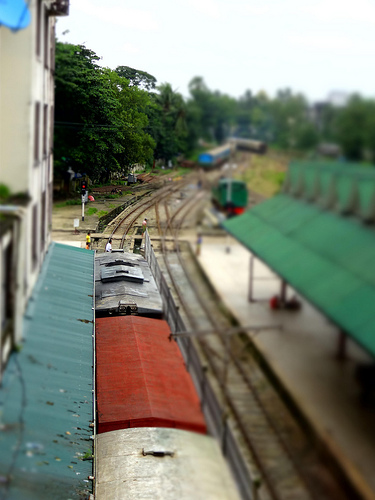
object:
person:
[86, 242, 90, 250]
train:
[92, 248, 245, 499]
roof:
[94, 251, 165, 316]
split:
[90, 232, 189, 242]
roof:
[0, 240, 95, 500]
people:
[75, 186, 94, 223]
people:
[86, 232, 91, 247]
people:
[106, 240, 112, 253]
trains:
[199, 141, 236, 171]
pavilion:
[220, 158, 375, 357]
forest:
[53, 42, 375, 206]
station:
[0, 160, 375, 500]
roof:
[92, 425, 243, 500]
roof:
[221, 157, 375, 355]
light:
[78, 181, 88, 221]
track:
[98, 171, 365, 499]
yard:
[59, 144, 374, 493]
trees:
[54, 42, 157, 192]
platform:
[189, 234, 375, 500]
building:
[0, 0, 68, 306]